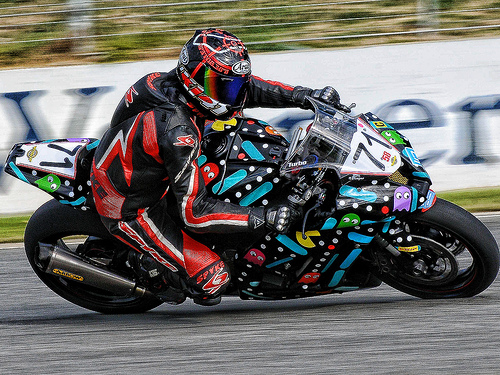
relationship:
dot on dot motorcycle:
[323, 248, 331, 260] [0, 95, 500, 314]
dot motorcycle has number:
[0, 95, 500, 314] [40, 139, 85, 174]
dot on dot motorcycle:
[232, 190, 242, 201] [0, 95, 500, 314]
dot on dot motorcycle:
[364, 203, 374, 215] [0, 95, 500, 314]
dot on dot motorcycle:
[353, 201, 366, 209] [0, 95, 500, 314]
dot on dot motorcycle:
[416, 195, 427, 203] [0, 95, 500, 314]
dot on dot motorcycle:
[367, 176, 380, 187] [0, 95, 500, 314]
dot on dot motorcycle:
[384, 181, 399, 190] [0, 95, 500, 314]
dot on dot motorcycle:
[319, 257, 327, 264] [0, 95, 500, 314]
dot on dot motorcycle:
[330, 233, 342, 245] [0, 95, 500, 314]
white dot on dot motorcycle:
[349, 201, 366, 215] [0, 95, 500, 314]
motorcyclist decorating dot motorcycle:
[90, 29, 341, 307] [0, 95, 500, 314]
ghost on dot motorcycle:
[335, 211, 360, 230] [0, 95, 500, 314]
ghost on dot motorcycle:
[388, 185, 410, 214] [0, 95, 500, 314]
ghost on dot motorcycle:
[296, 270, 321, 285] [0, 95, 500, 314]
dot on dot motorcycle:
[314, 260, 325, 271] [0, 95, 500, 314]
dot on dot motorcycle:
[233, 190, 243, 199] [0, 95, 500, 314]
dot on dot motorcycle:
[253, 175, 262, 181] [0, 95, 500, 314]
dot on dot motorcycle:
[28, 168, 38, 175] [0, 95, 500, 314]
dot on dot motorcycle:
[256, 125, 263, 134] [0, 95, 500, 314]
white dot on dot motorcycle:
[338, 197, 348, 212] [0, 95, 500, 314]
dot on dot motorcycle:
[365, 205, 373, 211] [0, 95, 500, 314]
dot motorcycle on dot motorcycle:
[373, 188, 395, 205] [0, 95, 500, 314]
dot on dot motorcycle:
[381, 180, 392, 190] [0, 95, 500, 314]